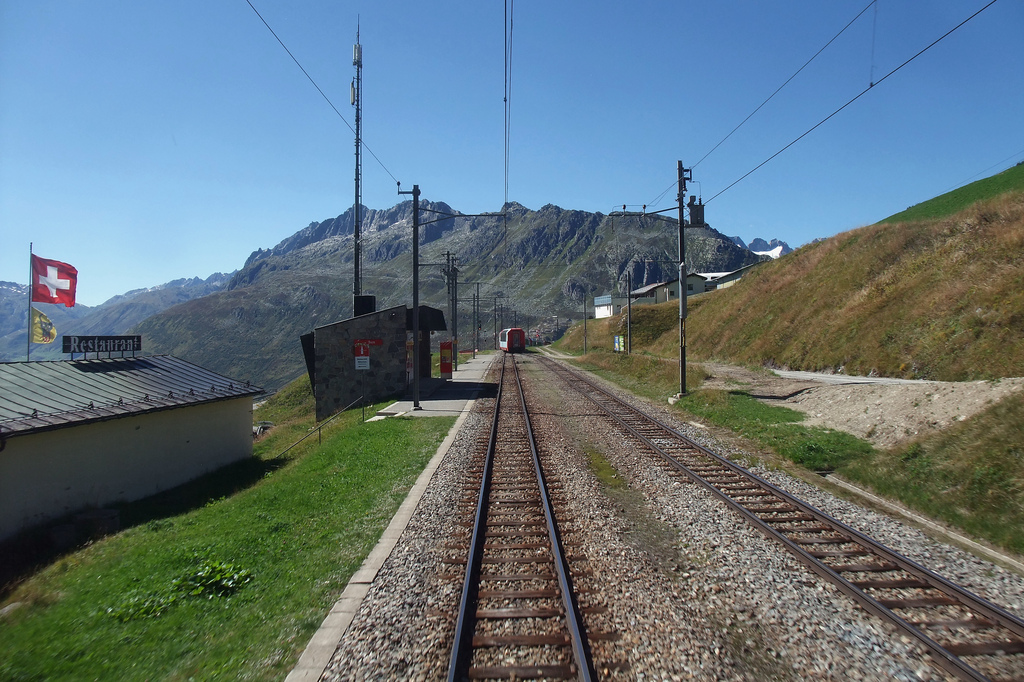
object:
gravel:
[547, 444, 755, 679]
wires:
[684, 0, 996, 218]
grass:
[584, 442, 656, 516]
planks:
[476, 607, 567, 619]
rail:
[447, 351, 594, 680]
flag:
[27, 241, 79, 361]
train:
[498, 328, 526, 352]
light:
[395, 182, 400, 192]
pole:
[668, 159, 688, 405]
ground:
[364, 355, 496, 423]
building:
[2, 335, 267, 542]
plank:
[485, 521, 543, 525]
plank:
[473, 634, 571, 646]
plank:
[799, 538, 870, 557]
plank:
[477, 590, 560, 597]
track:
[520, 353, 1023, 679]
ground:
[0, 162, 1022, 679]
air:
[0, 2, 1021, 308]